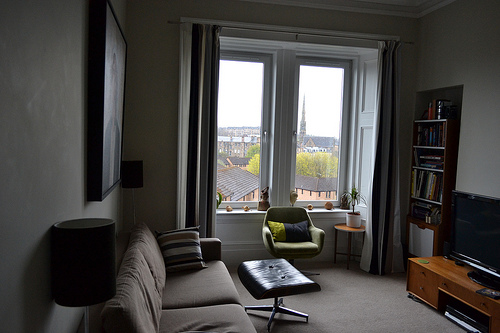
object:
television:
[448, 190, 498, 289]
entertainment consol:
[405, 256, 499, 331]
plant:
[340, 190, 365, 214]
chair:
[259, 205, 324, 278]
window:
[294, 62, 344, 201]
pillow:
[265, 219, 310, 241]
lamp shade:
[47, 218, 116, 308]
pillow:
[154, 225, 208, 275]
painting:
[92, 0, 126, 200]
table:
[330, 222, 369, 271]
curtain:
[186, 22, 221, 238]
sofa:
[95, 221, 259, 331]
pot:
[344, 211, 361, 228]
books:
[426, 172, 441, 199]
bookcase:
[405, 85, 463, 258]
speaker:
[439, 241, 451, 261]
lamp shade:
[119, 159, 146, 189]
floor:
[225, 266, 472, 332]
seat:
[233, 256, 322, 331]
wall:
[409, 0, 500, 282]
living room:
[1, 1, 500, 332]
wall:
[0, 0, 134, 329]